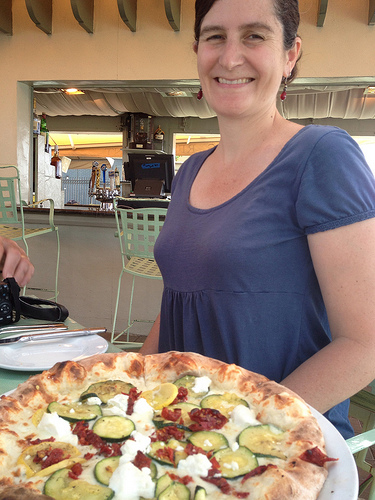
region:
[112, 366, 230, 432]
A zucchini and squash covered pizza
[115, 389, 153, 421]
A sun dried tomato sitting atop goat cheese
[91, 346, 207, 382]
Golden pizza crust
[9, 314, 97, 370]
Knives resting on a plate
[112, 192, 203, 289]
Pale blue bar stools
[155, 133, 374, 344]
A woman in a blue shirt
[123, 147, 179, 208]
The back of a computer moniter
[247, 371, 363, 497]
A large white round platter holding pizza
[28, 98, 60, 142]
Bottles near the ceiling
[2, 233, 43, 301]
A hand reaching toward the pizza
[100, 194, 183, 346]
tall chair with a white back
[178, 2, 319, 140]
smiling lady with brown hair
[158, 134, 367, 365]
torso of woman with blue shirt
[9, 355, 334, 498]
pizza with zucchini and cheese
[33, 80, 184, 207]
kitchen of a pizza restaurant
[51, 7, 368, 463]
lady carrying a pizza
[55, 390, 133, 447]
slices of cooked zucchini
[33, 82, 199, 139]
white awning outside a restaurant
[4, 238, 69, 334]
hand holding a black strap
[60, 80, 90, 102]
small recessed light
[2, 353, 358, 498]
a pizza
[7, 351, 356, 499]
a pizza on a platter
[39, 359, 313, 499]
squash is on the pizza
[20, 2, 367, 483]
a woman stands by the pizza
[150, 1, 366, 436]
the woman is smiling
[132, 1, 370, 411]
the woman is wearing a purple shirt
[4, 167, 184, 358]
tall green barstools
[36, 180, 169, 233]
a bar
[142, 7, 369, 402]
the woman has red earings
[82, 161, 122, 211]
beer taps are at the bar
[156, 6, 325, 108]
a woman wearing earrings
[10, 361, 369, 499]
a pizza on a white plate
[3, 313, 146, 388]
a white plate with silverware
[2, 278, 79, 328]
a black camera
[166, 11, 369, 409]
a woman wearing a blue dress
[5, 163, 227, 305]
blue bar chairs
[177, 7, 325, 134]
a woman smiling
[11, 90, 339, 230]
a bar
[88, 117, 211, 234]
a black cash register at a bar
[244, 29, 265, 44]
a person's eye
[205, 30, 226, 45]
a person's eye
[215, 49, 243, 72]
a person's nose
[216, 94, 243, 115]
a person's chin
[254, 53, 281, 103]
a person's cheek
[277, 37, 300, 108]
a person's ear with earring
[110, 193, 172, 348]
a blue chair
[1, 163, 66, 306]
a blue chair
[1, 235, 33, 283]
a person's hand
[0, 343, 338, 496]
a delicious looking pizza